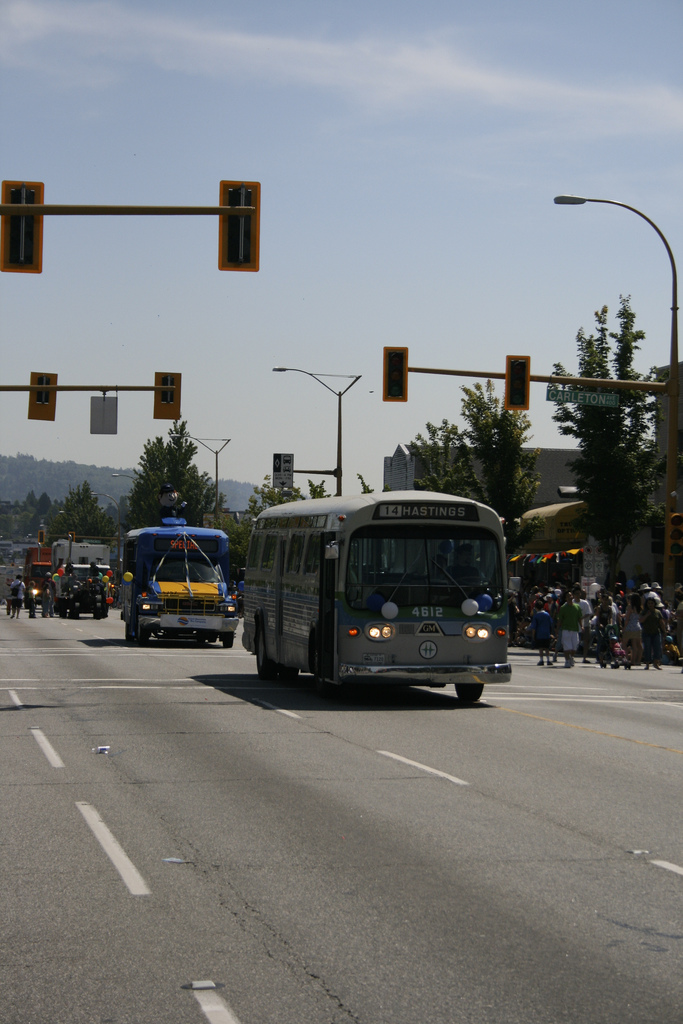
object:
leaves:
[602, 427, 636, 479]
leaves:
[411, 419, 453, 487]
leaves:
[459, 378, 495, 428]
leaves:
[513, 444, 543, 509]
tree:
[409, 378, 547, 551]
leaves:
[137, 414, 198, 468]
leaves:
[129, 436, 159, 494]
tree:
[119, 414, 228, 532]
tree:
[40, 479, 124, 553]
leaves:
[40, 504, 73, 547]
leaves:
[64, 480, 104, 516]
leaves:
[94, 517, 118, 553]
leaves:
[199, 471, 229, 514]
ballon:
[381, 602, 398, 619]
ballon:
[461, 599, 478, 616]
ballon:
[477, 594, 493, 611]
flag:
[510, 555, 522, 563]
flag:
[529, 553, 536, 562]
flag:
[542, 551, 554, 559]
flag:
[566, 548, 580, 554]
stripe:
[74, 800, 150, 898]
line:
[494, 706, 682, 752]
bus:
[120, 484, 244, 648]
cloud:
[0, 0, 683, 496]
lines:
[32, 726, 68, 769]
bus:
[241, 488, 521, 701]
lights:
[382, 347, 408, 402]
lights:
[153, 372, 181, 419]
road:
[0, 608, 683, 1024]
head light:
[477, 627, 488, 640]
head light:
[369, 627, 381, 638]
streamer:
[152, 531, 222, 599]